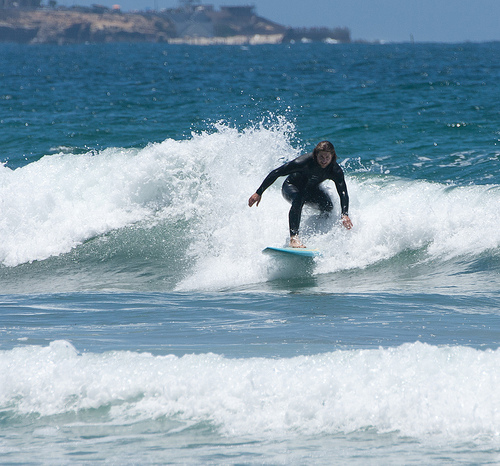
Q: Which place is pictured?
A: It is an ocean.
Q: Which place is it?
A: It is an ocean.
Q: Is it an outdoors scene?
A: Yes, it is outdoors.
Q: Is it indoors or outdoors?
A: It is outdoors.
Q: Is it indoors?
A: No, it is outdoors.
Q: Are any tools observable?
A: No, there are no tools.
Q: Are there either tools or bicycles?
A: No, there are no tools or bicycles.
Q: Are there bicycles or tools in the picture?
A: No, there are no tools or bicycles.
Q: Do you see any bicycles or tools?
A: No, there are no tools or bicycles.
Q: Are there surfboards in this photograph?
A: Yes, there is a surfboard.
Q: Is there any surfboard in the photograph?
A: Yes, there is a surfboard.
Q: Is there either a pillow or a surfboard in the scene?
A: Yes, there is a surfboard.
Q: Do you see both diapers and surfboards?
A: No, there is a surfboard but no diapers.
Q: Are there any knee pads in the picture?
A: No, there are no knee pads.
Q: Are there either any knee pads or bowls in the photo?
A: No, there are no knee pads or bowls.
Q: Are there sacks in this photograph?
A: No, there are no sacks.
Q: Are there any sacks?
A: No, there are no sacks.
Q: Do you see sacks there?
A: No, there are no sacks.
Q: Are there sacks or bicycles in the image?
A: No, there are no sacks or bicycles.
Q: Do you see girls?
A: No, there are no girls.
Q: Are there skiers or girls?
A: No, there are no girls or skiers.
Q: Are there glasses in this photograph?
A: No, there are no glasses.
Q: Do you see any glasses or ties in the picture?
A: No, there are no glasses or ties.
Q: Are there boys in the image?
A: No, there are no boys.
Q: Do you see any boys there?
A: No, there are no boys.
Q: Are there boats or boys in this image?
A: No, there are no boys or boats.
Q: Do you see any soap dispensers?
A: No, there are no soap dispensers.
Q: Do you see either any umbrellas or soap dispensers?
A: No, there are no soap dispensers or umbrellas.